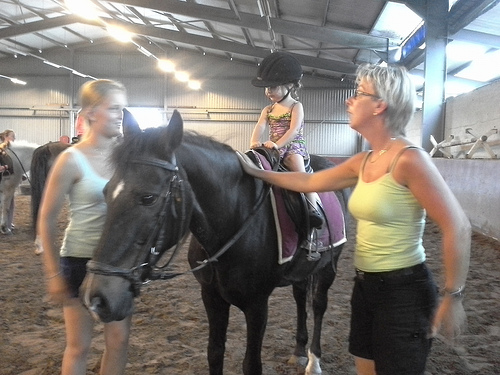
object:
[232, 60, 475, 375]
lady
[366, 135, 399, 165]
necklace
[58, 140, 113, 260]
tank top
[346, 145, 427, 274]
top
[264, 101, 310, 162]
dress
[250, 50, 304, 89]
helmet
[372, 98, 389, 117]
ear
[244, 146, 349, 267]
blanket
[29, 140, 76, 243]
horse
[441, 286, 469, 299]
watch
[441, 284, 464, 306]
wrist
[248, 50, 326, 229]
girl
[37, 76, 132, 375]
girl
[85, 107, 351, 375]
black horse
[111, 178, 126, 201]
white diamond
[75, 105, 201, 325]
head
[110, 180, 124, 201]
diamond